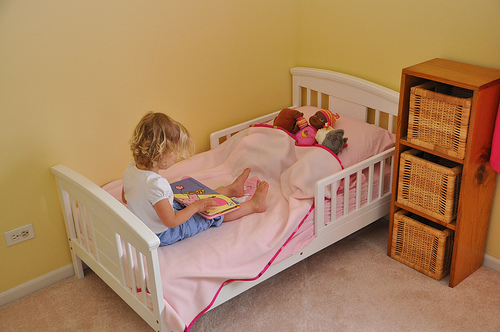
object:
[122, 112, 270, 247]
girl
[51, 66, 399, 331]
bed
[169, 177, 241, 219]
book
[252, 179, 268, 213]
foot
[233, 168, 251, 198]
foot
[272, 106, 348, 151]
stuffed animals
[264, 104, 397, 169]
pillow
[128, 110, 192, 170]
head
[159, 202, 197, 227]
arm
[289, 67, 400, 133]
headboard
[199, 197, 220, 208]
hand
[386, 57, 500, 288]
shelving unit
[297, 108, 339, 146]
baby doll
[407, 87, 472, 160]
basket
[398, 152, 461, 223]
basket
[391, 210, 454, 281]
basket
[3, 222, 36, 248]
outlet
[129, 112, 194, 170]
hair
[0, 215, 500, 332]
carpet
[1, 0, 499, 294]
walls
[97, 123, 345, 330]
blanket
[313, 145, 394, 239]
railing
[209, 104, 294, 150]
railing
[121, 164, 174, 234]
shirt